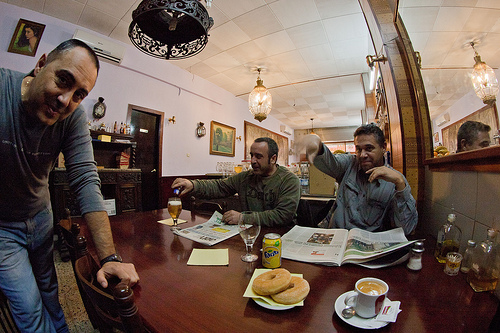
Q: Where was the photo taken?
A: In a restaurant.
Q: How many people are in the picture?
A: Three.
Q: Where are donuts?
A: On a plate.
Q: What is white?
A: A mug.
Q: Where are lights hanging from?
A: From the ceiling.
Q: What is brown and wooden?
A: Table.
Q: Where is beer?
A: In a glass.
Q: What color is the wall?
A: White.